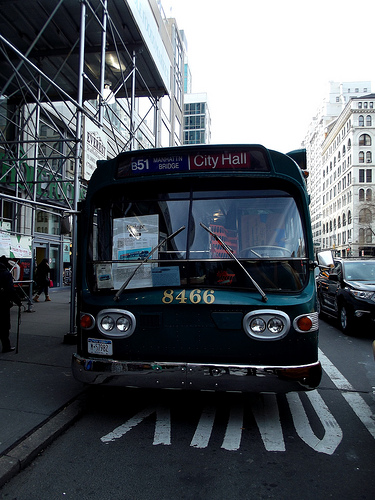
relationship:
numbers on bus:
[160, 284, 216, 305] [69, 145, 322, 394]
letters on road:
[101, 387, 343, 454] [0, 303, 374, 498]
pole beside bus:
[68, 0, 87, 344] [69, 145, 322, 394]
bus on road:
[69, 145, 322, 394] [0, 303, 374, 498]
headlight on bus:
[268, 320, 285, 335] [69, 145, 322, 394]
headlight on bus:
[250, 319, 267, 337] [69, 145, 322, 394]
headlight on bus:
[117, 316, 129, 333] [69, 145, 322, 394]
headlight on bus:
[100, 316, 114, 333] [69, 145, 322, 394]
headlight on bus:
[76, 311, 97, 335] [69, 145, 322, 394]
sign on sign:
[194, 153, 251, 169] [189, 149, 250, 169]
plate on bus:
[87, 336, 114, 357] [69, 145, 322, 394]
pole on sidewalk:
[68, 0, 87, 344] [0, 277, 93, 497]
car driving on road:
[313, 257, 374, 331] [0, 303, 374, 498]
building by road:
[299, 81, 373, 265] [0, 303, 374, 498]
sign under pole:
[0, 258, 36, 283] [68, 0, 87, 344]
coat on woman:
[32, 262, 51, 285] [32, 258, 56, 302]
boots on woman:
[29, 292, 54, 302] [32, 258, 56, 302]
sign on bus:
[189, 149, 250, 169] [69, 145, 322, 394]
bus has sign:
[69, 145, 322, 394] [189, 149, 250, 169]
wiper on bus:
[193, 218, 270, 307] [69, 145, 322, 394]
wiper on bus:
[114, 223, 188, 301] [69, 145, 322, 394]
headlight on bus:
[296, 316, 313, 333] [69, 145, 322, 394]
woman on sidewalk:
[32, 258, 56, 302] [0, 277, 93, 497]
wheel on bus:
[238, 245, 290, 259] [69, 145, 322, 394]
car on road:
[313, 257, 374, 331] [0, 303, 374, 498]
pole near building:
[68, 0, 87, 344] [299, 81, 373, 265]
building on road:
[299, 81, 373, 265] [0, 303, 374, 498]